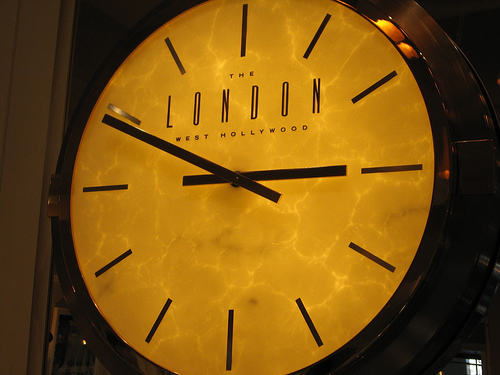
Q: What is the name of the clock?
A: London.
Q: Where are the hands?
A: The clock.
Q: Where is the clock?
A: Wall.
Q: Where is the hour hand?
A: 3.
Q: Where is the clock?
A: Building.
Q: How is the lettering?
A: Black.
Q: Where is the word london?
A: Clock.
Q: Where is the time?
A: Clock.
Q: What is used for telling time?
A: Clock.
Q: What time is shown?
A: 2:49.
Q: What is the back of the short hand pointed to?
A: 9.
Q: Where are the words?
A: Above the short hand.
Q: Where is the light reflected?
A: Top right corner.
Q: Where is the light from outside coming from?
A: Window in the bottom right corner.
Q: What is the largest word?
A: LONDON.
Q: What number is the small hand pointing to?
A: 3.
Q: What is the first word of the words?
A: The.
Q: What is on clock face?
A: Black lines.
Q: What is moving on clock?
A: Hands.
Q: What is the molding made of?
A: Wood.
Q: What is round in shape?
A: Clock face.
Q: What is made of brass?
A: Clock.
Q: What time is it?
A: 2:49.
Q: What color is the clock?
A: Yellow.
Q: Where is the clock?
A: The london west hollywood.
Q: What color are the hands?
A: Black.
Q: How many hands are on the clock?
A: 2.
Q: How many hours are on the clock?
A: 12.